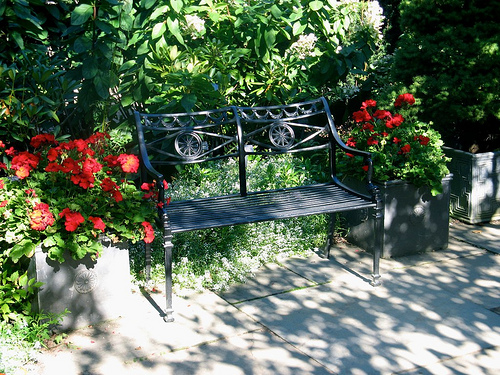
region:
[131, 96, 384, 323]
Black metal bench on the concrete.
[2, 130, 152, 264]
Red flowers beside the bench.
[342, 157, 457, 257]
Gray flower planter on the ground.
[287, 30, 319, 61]
White flowers on the tree.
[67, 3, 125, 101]
Green leaves on the tree.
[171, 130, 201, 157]
Wheel design on the bench.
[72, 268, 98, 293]
Circle design on the planter.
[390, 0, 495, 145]
Tree in the background.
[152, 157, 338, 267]
Bush with white flowers behind bench.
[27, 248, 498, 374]
Black shadows on the pavement.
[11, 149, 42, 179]
red flower in garden box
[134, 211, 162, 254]
red flower in garden box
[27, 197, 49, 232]
red flower in garden box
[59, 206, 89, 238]
red flower in garden box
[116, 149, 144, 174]
red flower in garden box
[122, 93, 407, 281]
black bench between garden boxes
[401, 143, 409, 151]
red flower in garden box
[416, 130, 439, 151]
red flower in garden box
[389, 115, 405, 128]
red flower in garden box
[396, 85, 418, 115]
red flower in garden box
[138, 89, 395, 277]
black metal bench on a sidewalk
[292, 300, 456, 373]
grey stone surface of the sidewalk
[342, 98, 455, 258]
rose bush in a square planter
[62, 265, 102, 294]
grey emblem on the planter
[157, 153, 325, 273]
white flowers growing behind the bench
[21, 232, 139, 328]
grey square planter next to the bench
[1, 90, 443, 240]
roses growing next to the bench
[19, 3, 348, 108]
several plants growing behind the bench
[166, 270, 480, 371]
shadows of tree branches on the ground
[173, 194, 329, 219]
black metal slats of the bench seat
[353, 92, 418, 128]
The flowers are red in color.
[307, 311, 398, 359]
The pavement is light in color.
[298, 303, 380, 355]
The pavement is made from concrete.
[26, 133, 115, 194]
The flowers on the bush are red.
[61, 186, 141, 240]
The leaves on the bush are green.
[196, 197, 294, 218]
The bench seat is dark in color.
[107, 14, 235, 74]
The bushes in the background are green.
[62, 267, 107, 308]
The planter is made from concrete.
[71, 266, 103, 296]
The symbol on the planter is a circle.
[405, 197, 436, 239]
The planter is grey in color.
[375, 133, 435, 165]
flowers in a pot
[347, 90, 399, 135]
flowers in a pot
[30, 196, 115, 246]
flowers in a pot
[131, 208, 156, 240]
flower in a pot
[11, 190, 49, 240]
flower in a pot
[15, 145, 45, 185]
flower in a pot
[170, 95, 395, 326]
black bench near flower pots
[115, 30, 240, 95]
tree leaves near bench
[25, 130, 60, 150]
flower in a pot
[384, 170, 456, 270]
pot of red flowers